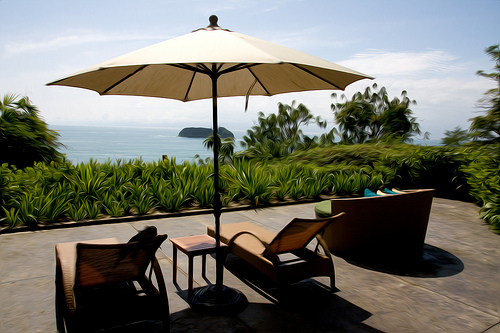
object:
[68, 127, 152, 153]
blue ocean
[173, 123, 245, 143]
rock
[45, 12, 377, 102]
umbrella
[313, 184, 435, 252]
chair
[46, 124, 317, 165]
ocean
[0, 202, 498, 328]
porch